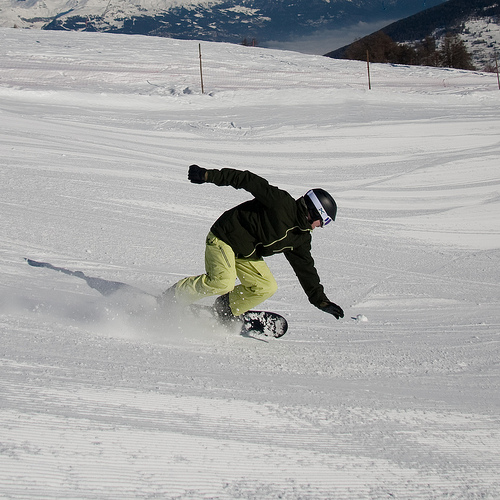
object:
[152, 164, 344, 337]
man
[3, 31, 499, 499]
slope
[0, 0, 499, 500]
snow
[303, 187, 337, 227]
helmet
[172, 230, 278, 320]
pants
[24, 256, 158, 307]
shadow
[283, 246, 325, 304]
arm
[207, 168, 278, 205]
arm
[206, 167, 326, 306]
jacket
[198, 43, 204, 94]
pole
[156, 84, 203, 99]
pile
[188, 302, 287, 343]
snowboard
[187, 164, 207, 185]
glove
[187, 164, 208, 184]
hand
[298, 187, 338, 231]
head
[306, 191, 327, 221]
stripe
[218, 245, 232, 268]
zipper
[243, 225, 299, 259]
stripe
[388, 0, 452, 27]
ridge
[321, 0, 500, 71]
mountain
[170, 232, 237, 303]
leg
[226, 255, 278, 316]
leg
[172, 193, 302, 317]
body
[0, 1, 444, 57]
mountains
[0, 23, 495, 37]
horizon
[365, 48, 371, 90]
pole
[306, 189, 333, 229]
goggles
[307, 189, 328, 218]
band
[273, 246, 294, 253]
zipper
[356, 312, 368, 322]
ball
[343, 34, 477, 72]
trees